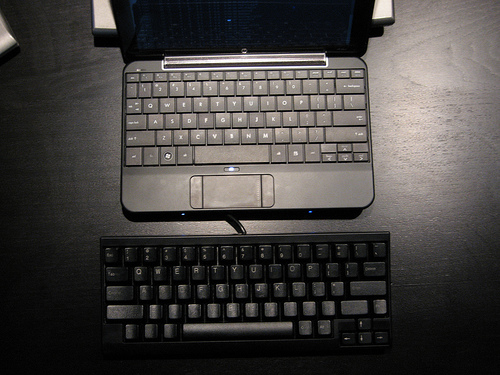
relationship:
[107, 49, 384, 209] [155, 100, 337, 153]
laptop black keyboard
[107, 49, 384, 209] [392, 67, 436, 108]
laptop on table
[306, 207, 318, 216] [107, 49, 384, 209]
light on laptop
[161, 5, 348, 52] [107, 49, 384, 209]
screen on laptop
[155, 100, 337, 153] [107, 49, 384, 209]
keyboard on laptop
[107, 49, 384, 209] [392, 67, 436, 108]
laptop sitting on table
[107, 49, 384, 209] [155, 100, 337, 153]
laptop on keyboard